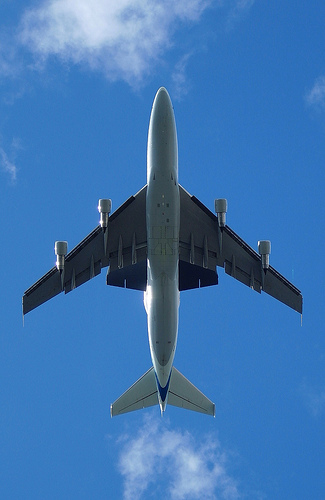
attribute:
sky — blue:
[16, 22, 147, 151]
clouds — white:
[305, 73, 324, 100]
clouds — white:
[171, 69, 187, 85]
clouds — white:
[172, 48, 194, 70]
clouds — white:
[50, 1, 130, 48]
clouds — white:
[0, 148, 19, 178]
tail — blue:
[110, 288, 219, 421]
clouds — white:
[17, 1, 207, 96]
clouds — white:
[118, 416, 239, 498]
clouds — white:
[21, 1, 231, 95]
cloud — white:
[0, 0, 209, 97]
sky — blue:
[1, 0, 324, 498]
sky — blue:
[221, 323, 309, 489]